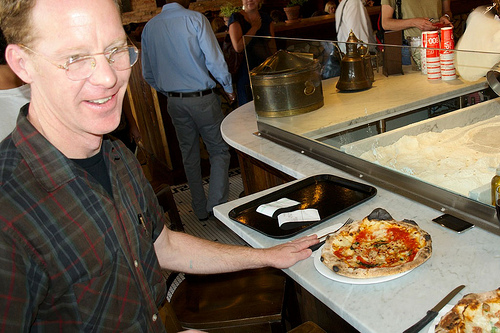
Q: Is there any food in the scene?
A: Yes, there is food.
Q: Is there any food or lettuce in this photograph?
A: Yes, there is food.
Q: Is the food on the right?
A: Yes, the food is on the right of the image.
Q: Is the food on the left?
A: No, the food is on the right of the image.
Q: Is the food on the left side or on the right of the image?
A: The food is on the right of the image.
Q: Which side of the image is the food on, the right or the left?
A: The food is on the right of the image.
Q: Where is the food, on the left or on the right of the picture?
A: The food is on the right of the image.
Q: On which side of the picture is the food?
A: The food is on the right of the image.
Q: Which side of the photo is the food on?
A: The food is on the right of the image.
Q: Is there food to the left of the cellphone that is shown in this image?
A: Yes, there is food to the left of the cellphone.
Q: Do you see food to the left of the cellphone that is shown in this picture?
A: Yes, there is food to the left of the cellphone.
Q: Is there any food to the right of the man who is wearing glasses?
A: Yes, there is food to the right of the man.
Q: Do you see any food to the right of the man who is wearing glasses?
A: Yes, there is food to the right of the man.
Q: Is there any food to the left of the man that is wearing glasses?
A: No, the food is to the right of the man.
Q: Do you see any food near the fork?
A: Yes, there is food near the fork.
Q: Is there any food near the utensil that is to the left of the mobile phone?
A: Yes, there is food near the fork.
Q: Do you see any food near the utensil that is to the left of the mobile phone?
A: Yes, there is food near the fork.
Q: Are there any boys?
A: No, there are no boys.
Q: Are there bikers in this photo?
A: No, there are no bikers.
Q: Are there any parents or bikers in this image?
A: No, there are no bikers or parents.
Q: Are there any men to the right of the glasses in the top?
A: Yes, there is a man to the right of the glasses.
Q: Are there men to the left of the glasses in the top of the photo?
A: No, the man is to the right of the glasses.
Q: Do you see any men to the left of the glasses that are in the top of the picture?
A: No, the man is to the right of the glasses.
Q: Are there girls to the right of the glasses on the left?
A: No, there is a man to the right of the glasses.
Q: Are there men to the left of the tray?
A: Yes, there is a man to the left of the tray.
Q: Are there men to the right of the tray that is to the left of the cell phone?
A: No, the man is to the left of the tray.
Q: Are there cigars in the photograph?
A: No, there are no cigars.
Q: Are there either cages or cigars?
A: No, there are no cigars or cages.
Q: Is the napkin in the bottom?
A: Yes, the napkin is in the bottom of the image.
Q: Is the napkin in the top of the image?
A: No, the napkin is in the bottom of the image.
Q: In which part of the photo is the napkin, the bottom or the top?
A: The napkin is in the bottom of the image.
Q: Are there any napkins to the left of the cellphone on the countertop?
A: Yes, there is a napkin to the left of the mobile phone.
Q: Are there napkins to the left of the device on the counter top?
A: Yes, there is a napkin to the left of the mobile phone.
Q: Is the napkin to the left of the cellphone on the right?
A: Yes, the napkin is to the left of the cellphone.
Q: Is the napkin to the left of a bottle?
A: No, the napkin is to the left of the cellphone.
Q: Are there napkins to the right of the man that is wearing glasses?
A: Yes, there is a napkin to the right of the man.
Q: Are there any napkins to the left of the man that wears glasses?
A: No, the napkin is to the right of the man.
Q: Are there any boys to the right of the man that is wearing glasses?
A: No, there is a napkin to the right of the man.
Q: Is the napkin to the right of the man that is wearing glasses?
A: Yes, the napkin is to the right of the man.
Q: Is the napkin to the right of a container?
A: No, the napkin is to the right of the man.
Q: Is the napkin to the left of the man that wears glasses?
A: No, the napkin is to the right of the man.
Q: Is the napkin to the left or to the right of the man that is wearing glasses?
A: The napkin is to the right of the man.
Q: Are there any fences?
A: No, there are no fences.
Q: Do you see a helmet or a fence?
A: No, there are no fences or helmets.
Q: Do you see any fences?
A: No, there are no fences.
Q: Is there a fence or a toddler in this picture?
A: No, there are no fences or toddlers.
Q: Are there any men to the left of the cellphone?
A: Yes, there is a man to the left of the cellphone.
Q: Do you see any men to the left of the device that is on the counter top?
A: Yes, there is a man to the left of the cellphone.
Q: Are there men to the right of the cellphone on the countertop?
A: No, the man is to the left of the cellphone.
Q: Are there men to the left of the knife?
A: Yes, there is a man to the left of the knife.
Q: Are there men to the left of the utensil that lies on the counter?
A: Yes, there is a man to the left of the knife.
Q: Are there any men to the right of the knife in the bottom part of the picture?
A: No, the man is to the left of the knife.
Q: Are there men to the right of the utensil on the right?
A: No, the man is to the left of the knife.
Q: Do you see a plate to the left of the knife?
A: No, there is a man to the left of the knife.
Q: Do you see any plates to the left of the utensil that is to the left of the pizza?
A: No, there is a man to the left of the knife.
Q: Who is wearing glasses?
A: The man is wearing glasses.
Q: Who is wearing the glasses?
A: The man is wearing glasses.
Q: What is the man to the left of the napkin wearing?
A: The man is wearing glasses.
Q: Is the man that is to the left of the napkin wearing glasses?
A: Yes, the man is wearing glasses.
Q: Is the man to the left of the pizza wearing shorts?
A: No, the man is wearing glasses.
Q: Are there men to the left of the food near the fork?
A: Yes, there is a man to the left of the food.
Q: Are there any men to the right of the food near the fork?
A: No, the man is to the left of the food.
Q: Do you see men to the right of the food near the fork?
A: No, the man is to the left of the food.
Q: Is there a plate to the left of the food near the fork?
A: No, there is a man to the left of the food.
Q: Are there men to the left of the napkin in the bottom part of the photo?
A: Yes, there is a man to the left of the napkin.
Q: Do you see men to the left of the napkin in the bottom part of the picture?
A: Yes, there is a man to the left of the napkin.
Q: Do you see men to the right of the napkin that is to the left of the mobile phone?
A: No, the man is to the left of the napkin.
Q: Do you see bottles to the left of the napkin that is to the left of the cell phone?
A: No, there is a man to the left of the napkin.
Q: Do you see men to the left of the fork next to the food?
A: Yes, there is a man to the left of the fork.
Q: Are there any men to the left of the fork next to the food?
A: Yes, there is a man to the left of the fork.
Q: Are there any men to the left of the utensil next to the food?
A: Yes, there is a man to the left of the fork.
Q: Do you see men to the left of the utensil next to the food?
A: Yes, there is a man to the left of the fork.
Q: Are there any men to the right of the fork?
A: No, the man is to the left of the fork.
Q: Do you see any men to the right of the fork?
A: No, the man is to the left of the fork.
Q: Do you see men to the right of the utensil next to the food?
A: No, the man is to the left of the fork.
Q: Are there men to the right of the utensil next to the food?
A: No, the man is to the left of the fork.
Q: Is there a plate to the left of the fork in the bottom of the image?
A: No, there is a man to the left of the fork.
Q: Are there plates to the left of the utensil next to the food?
A: No, there is a man to the left of the fork.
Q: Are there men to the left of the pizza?
A: Yes, there is a man to the left of the pizza.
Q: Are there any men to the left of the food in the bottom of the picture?
A: Yes, there is a man to the left of the pizza.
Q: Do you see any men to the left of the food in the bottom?
A: Yes, there is a man to the left of the pizza.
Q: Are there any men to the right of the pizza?
A: No, the man is to the left of the pizza.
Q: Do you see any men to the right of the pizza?
A: No, the man is to the left of the pizza.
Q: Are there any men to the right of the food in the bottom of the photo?
A: No, the man is to the left of the pizza.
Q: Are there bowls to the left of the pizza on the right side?
A: No, there is a man to the left of the pizza.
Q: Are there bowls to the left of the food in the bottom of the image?
A: No, there is a man to the left of the pizza.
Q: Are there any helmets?
A: No, there are no helmets.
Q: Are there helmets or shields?
A: No, there are no helmets or shields.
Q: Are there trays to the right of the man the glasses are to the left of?
A: Yes, there is a tray to the right of the man.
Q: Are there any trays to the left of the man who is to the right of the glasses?
A: No, the tray is to the right of the man.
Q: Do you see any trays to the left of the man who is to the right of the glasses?
A: No, the tray is to the right of the man.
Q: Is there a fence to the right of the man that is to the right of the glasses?
A: No, there is a tray to the right of the man.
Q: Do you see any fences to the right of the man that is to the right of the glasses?
A: No, there is a tray to the right of the man.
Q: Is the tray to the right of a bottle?
A: No, the tray is to the right of the man.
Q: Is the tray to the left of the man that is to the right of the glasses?
A: No, the tray is to the right of the man.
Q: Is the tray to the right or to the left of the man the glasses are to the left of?
A: The tray is to the right of the man.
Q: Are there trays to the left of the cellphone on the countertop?
A: Yes, there is a tray to the left of the cellphone.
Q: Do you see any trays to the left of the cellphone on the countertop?
A: Yes, there is a tray to the left of the cellphone.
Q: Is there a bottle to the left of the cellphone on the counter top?
A: No, there is a tray to the left of the cell phone.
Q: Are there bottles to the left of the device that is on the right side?
A: No, there is a tray to the left of the cell phone.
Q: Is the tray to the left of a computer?
A: No, the tray is to the left of the cell phone.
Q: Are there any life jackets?
A: No, there are no life jackets.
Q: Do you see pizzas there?
A: Yes, there is a pizza.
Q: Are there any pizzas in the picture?
A: Yes, there is a pizza.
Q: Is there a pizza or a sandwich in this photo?
A: Yes, there is a pizza.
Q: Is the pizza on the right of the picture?
A: Yes, the pizza is on the right of the image.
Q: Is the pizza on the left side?
A: No, the pizza is on the right of the image.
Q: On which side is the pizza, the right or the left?
A: The pizza is on the right of the image.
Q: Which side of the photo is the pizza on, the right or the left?
A: The pizza is on the right of the image.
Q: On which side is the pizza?
A: The pizza is on the right of the image.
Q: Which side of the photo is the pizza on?
A: The pizza is on the right of the image.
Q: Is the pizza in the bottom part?
A: Yes, the pizza is in the bottom of the image.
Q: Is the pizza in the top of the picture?
A: No, the pizza is in the bottom of the image.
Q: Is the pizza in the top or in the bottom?
A: The pizza is in the bottom of the image.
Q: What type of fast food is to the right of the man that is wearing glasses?
A: The food is a pizza.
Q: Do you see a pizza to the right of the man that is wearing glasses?
A: Yes, there is a pizza to the right of the man.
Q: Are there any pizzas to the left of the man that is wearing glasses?
A: No, the pizza is to the right of the man.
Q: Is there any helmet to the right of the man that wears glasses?
A: No, there is a pizza to the right of the man.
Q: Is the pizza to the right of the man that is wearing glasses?
A: Yes, the pizza is to the right of the man.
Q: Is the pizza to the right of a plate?
A: No, the pizza is to the right of the man.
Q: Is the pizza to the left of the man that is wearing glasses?
A: No, the pizza is to the right of the man.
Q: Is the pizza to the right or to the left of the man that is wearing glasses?
A: The pizza is to the right of the man.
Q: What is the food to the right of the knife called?
A: The food is a pizza.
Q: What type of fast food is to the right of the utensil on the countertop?
A: The food is a pizza.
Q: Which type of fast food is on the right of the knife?
A: The food is a pizza.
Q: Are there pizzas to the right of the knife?
A: Yes, there is a pizza to the right of the knife.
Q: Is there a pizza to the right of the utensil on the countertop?
A: Yes, there is a pizza to the right of the knife.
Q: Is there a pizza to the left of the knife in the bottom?
A: No, the pizza is to the right of the knife.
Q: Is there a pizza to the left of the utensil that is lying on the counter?
A: No, the pizza is to the right of the knife.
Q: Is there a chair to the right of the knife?
A: No, there is a pizza to the right of the knife.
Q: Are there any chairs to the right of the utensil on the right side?
A: No, there is a pizza to the right of the knife.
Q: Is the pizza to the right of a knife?
A: Yes, the pizza is to the right of a knife.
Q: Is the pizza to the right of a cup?
A: No, the pizza is to the right of a knife.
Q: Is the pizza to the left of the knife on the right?
A: No, the pizza is to the right of the knife.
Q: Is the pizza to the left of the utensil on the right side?
A: No, the pizza is to the right of the knife.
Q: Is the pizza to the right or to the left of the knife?
A: The pizza is to the right of the knife.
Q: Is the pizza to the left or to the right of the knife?
A: The pizza is to the right of the knife.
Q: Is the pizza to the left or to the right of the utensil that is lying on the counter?
A: The pizza is to the right of the knife.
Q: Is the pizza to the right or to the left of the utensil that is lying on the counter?
A: The pizza is to the right of the knife.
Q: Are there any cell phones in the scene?
A: Yes, there is a cell phone.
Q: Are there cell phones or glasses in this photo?
A: Yes, there is a cell phone.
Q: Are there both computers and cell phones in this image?
A: No, there is a cell phone but no computers.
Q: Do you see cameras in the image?
A: No, there are no cameras.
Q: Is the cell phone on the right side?
A: Yes, the cell phone is on the right of the image.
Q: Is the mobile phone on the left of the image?
A: No, the mobile phone is on the right of the image.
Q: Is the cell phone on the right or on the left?
A: The cell phone is on the right of the image.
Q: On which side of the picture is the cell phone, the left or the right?
A: The cell phone is on the right of the image.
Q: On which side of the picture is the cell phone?
A: The cell phone is on the right of the image.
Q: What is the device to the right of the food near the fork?
A: The device is a cell phone.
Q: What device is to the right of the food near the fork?
A: The device is a cell phone.